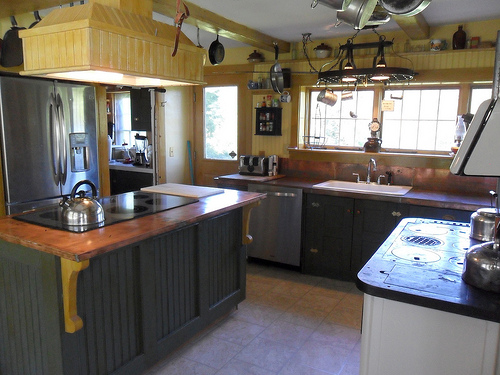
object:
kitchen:
[3, 26, 500, 349]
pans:
[208, 40, 225, 66]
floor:
[251, 279, 347, 364]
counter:
[413, 189, 467, 210]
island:
[169, 171, 237, 238]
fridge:
[2, 83, 100, 206]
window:
[298, 81, 372, 155]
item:
[470, 38, 481, 48]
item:
[431, 35, 445, 51]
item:
[483, 38, 493, 49]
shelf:
[413, 49, 492, 75]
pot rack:
[316, 35, 419, 89]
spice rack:
[254, 96, 283, 137]